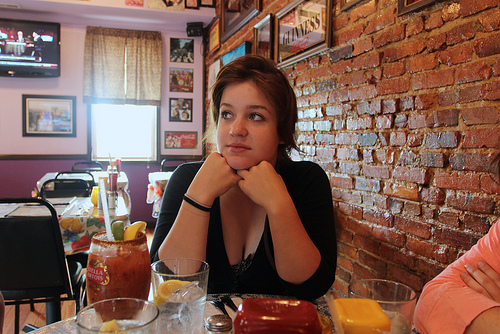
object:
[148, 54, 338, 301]
woman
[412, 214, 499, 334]
shirt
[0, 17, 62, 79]
television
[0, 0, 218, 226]
wall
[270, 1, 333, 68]
sign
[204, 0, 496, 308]
wall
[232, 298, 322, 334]
bottle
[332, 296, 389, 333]
mustard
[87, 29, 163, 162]
window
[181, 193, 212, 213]
wristband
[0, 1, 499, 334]
restaurant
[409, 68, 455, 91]
brick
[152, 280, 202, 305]
lemon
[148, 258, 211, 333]
glass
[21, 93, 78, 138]
photo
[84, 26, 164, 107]
curtain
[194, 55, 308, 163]
hair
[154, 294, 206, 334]
water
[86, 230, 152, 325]
glass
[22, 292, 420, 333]
table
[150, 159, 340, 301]
blouse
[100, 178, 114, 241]
straw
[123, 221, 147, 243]
lemon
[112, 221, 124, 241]
lime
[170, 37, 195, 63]
picture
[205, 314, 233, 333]
shaker